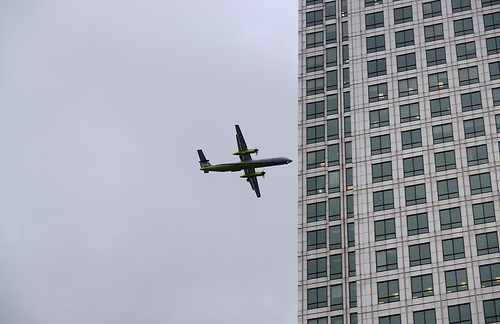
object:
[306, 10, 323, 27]
window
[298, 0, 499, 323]
building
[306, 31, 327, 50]
window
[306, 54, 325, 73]
window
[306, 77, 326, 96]
window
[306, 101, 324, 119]
window